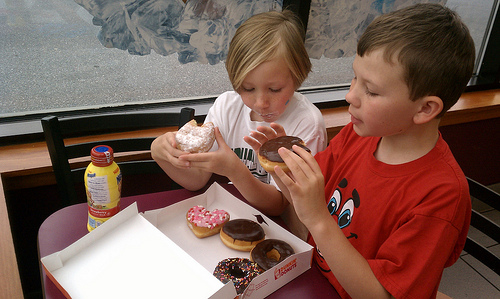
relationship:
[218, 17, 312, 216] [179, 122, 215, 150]
kid eating donut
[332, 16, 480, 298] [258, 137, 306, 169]
kid eating donut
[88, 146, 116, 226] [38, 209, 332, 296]
bottle on table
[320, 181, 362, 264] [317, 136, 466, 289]
smiley face on shirt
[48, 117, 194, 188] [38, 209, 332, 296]
chair at table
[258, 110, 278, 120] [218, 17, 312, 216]
sugar on kid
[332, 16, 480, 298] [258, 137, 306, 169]
boy holding donut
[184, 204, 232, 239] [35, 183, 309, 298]
donuts in donut box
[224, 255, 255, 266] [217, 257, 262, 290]
sprinkles on top of donut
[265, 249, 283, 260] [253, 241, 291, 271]
hole in donut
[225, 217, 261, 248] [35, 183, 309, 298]
donut in donut box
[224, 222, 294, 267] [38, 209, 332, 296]
donuts in box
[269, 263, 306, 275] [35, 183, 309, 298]
label on box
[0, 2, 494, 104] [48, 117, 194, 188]
window behind chair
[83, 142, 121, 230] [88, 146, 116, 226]
bottle of chocolate milk